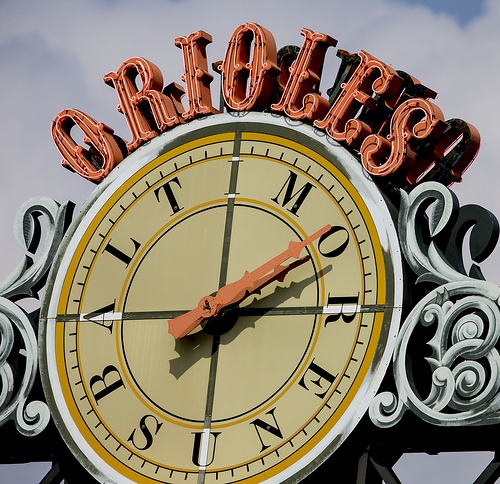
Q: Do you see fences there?
A: No, there are no fences.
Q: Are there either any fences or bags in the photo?
A: No, there are no fences or bags.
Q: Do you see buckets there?
A: No, there are no buckets.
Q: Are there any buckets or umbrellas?
A: No, there are no buckets or umbrellas.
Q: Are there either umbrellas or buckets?
A: No, there are no buckets or umbrellas.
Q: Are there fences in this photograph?
A: No, there are no fences.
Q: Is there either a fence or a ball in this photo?
A: No, there are no fences or balls.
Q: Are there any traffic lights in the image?
A: No, there are no traffic lights.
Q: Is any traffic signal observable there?
A: No, there are no traffic lights.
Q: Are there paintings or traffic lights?
A: No, there are no traffic lights or paintings.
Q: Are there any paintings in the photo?
A: No, there are no paintings.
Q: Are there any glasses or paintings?
A: No, there are no paintings or glasses.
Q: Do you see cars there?
A: No, there are no cars.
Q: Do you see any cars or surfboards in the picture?
A: No, there are no cars or surfboards.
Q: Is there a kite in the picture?
A: No, there are no kites.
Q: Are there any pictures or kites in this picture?
A: No, there are no kites or pictures.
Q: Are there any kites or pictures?
A: No, there are no kites or pictures.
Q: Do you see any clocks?
A: Yes, there is a clock.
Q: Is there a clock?
A: Yes, there is a clock.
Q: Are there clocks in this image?
A: Yes, there is a clock.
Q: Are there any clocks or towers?
A: Yes, there is a clock.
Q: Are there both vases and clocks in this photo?
A: No, there is a clock but no vases.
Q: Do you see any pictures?
A: No, there are no pictures.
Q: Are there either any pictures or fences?
A: No, there are no pictures or fences.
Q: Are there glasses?
A: No, there are no glasses.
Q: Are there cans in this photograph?
A: No, there are no cans.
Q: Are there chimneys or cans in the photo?
A: No, there are no cans or chimneys.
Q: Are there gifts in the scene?
A: No, there are no gifts.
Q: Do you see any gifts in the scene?
A: No, there are no gifts.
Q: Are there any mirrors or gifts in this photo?
A: No, there are no gifts or mirrors.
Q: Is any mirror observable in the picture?
A: No, there are no mirrors.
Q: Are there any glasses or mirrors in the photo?
A: No, there are no mirrors or glasses.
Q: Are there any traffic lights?
A: No, there are no traffic lights.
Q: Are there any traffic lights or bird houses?
A: No, there are no traffic lights or bird houses.